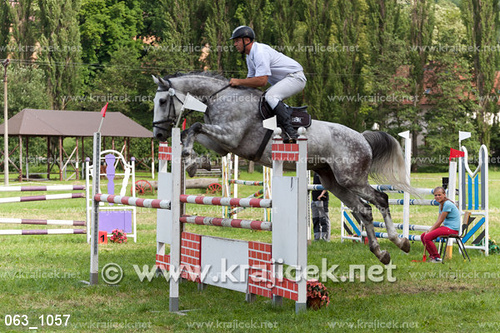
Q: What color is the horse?
A: Grey.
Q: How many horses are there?
A: One.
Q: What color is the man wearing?
A: White.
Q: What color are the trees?
A: Green.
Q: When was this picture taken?
A: During the day time.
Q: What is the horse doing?
A: Leaping.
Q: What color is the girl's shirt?
A: Blue.